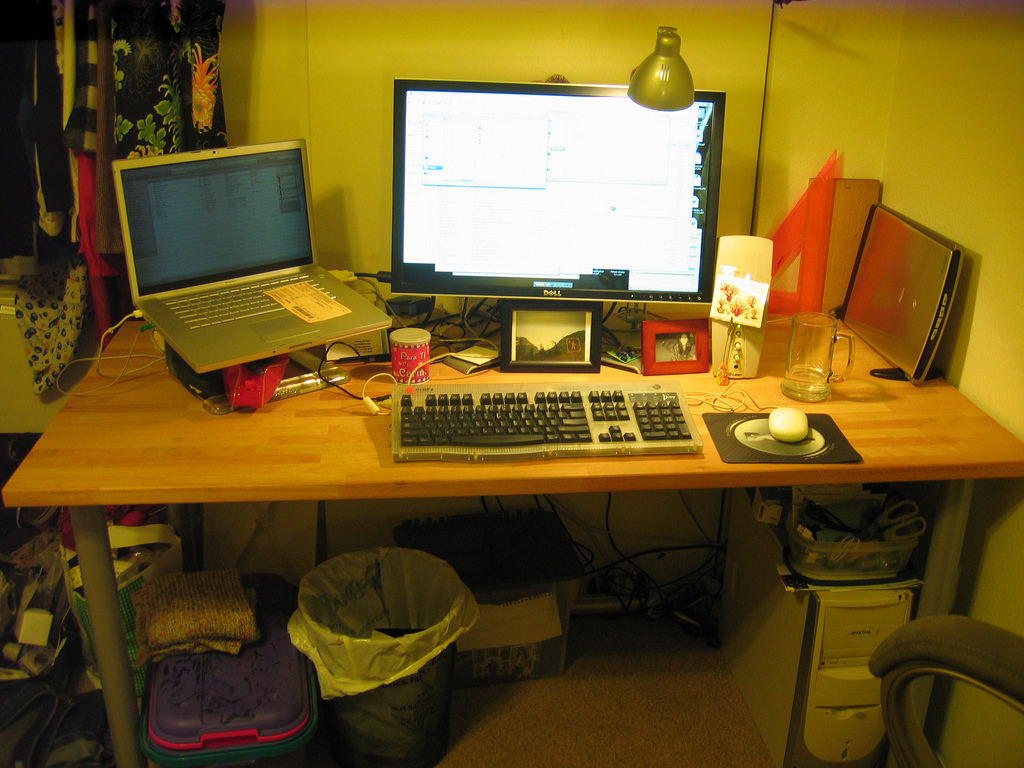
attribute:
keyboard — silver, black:
[385, 369, 703, 455]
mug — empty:
[772, 305, 853, 401]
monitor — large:
[390, 72, 730, 330]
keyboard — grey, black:
[398, 372, 703, 459]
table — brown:
[0, 270, 1022, 502]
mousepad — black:
[707, 400, 857, 464]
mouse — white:
[757, 398, 808, 441]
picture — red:
[638, 311, 714, 370]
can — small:
[287, 540, 472, 765]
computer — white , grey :
[745, 521, 901, 757]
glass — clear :
[775, 302, 862, 397]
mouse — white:
[751, 390, 828, 449]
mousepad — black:
[687, 397, 866, 473]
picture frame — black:
[486, 281, 629, 372]